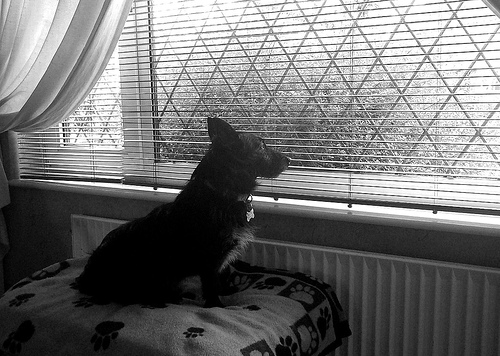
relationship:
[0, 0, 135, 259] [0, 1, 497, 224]
curtain over window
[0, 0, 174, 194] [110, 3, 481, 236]
curtain over window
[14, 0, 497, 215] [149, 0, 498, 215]
blinds over window